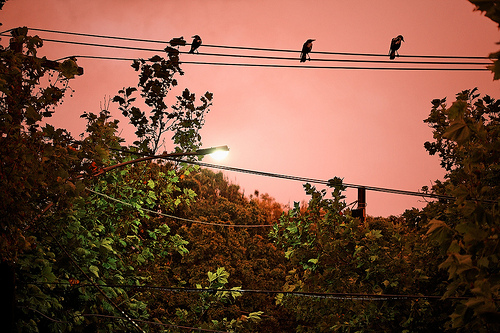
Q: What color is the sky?
A: Pink.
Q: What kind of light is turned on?
A: A street light.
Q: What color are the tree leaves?
A: Green.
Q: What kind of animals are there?
A: Birds.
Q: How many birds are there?
A: Three.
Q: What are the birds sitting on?
A: Wires.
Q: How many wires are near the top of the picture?
A: Three.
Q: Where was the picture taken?
A: In a wooded area.